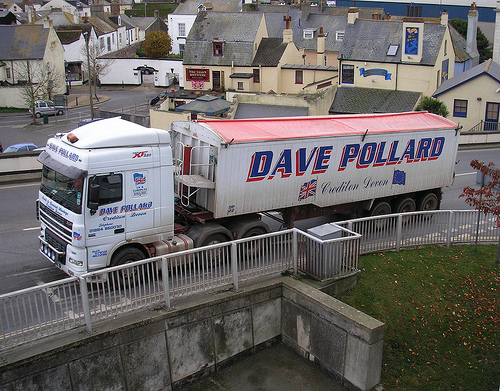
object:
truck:
[37, 111, 462, 288]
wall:
[0, 275, 384, 390]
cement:
[165, 324, 215, 384]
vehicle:
[29, 99, 66, 118]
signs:
[358, 67, 392, 80]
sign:
[185, 67, 210, 82]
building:
[183, 12, 339, 91]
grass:
[330, 243, 499, 390]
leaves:
[419, 259, 498, 340]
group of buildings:
[1, 0, 500, 135]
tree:
[79, 35, 114, 118]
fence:
[0, 209, 499, 360]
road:
[0, 148, 500, 338]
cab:
[35, 115, 176, 290]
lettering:
[98, 200, 154, 216]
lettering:
[245, 135, 446, 183]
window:
[213, 41, 223, 57]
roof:
[171, 110, 462, 146]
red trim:
[245, 139, 442, 183]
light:
[67, 132, 79, 143]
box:
[307, 223, 343, 278]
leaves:
[456, 158, 499, 229]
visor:
[36, 152, 88, 181]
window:
[41, 162, 81, 214]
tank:
[150, 232, 195, 270]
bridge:
[3, 250, 386, 390]